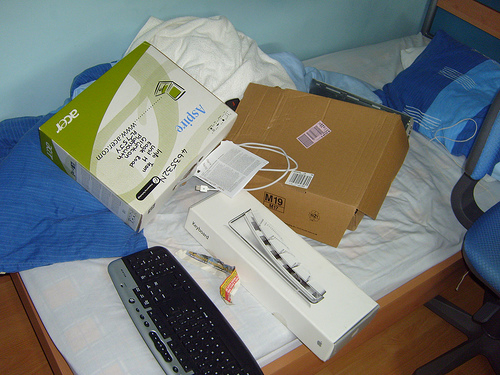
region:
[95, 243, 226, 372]
a black and silver keyboard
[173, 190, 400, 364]
a white and silver box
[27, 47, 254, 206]
a green and white box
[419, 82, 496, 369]
a blue and black computer chair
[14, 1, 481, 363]
a small twin size bed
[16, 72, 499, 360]
a tan bed with white sheets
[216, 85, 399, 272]
a brown shipping box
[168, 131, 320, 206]
a white cord that plugs into a computer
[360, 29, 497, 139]
a pillow case with shades of blue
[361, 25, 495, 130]
a pillow case with dark blue and light blue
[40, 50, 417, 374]
Computer arrives open boxes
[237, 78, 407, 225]
Cardboard box all came in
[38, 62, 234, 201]
Acer Aspire computer box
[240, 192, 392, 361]
White computer keyboard box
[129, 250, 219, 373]
Black and gray computer keyboard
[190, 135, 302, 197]
Instructions USB connector cord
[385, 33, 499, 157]
Bed pillow blue stripes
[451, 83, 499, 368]
Comfortable office swivel chair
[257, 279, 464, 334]
Wooden twin bed frame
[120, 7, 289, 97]
Thrown crumpled white blanket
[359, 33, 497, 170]
two tone blue pillow on bed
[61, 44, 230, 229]
Acer Aspire laptop box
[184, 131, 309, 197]
white computer wire on box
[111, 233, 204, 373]
silver and black keyboard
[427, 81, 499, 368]
blue and black chair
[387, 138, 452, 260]
wrinkled white sheet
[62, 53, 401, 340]
three boxes on bed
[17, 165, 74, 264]
blue comforter on bed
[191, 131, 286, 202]
computer pamphlet for instructions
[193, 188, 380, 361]
white keyboard box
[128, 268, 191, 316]
black keys on keyboard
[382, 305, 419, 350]
two tone brown counter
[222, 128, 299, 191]
white computer cord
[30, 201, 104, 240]
crinkled blue paper on counter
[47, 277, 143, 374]
white paper on the counter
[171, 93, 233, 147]
blue bold words on box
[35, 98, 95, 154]
green area on box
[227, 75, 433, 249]
brown card board box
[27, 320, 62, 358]
brown edge on board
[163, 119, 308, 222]
white instructions on surface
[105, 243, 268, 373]
a black and gray keyboard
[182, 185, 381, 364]
a white cardboard box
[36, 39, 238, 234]
a green and gray cardboard box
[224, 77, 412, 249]
a brown cardboard box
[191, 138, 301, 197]
a white computer cord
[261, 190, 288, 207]
black writing on the box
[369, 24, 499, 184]
a blue pillow on the bed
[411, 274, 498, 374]
the black base of a chair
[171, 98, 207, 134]
blue writing on the box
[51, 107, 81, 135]
white writing on the box